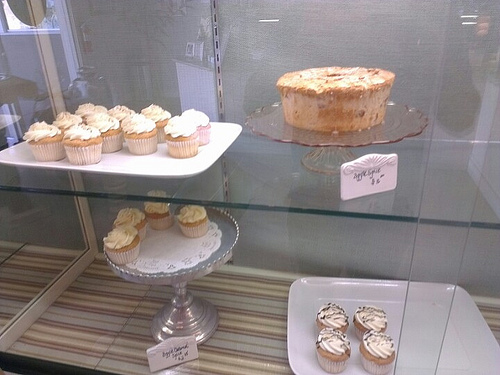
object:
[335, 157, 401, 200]
sign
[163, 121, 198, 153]
cupcake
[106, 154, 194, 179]
plate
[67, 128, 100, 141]
frosting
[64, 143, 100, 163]
cupcake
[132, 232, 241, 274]
platter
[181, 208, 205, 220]
frosting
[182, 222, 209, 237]
cupcake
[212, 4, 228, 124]
beam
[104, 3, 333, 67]
wall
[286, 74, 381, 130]
cake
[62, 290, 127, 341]
wall paper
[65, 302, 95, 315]
stripe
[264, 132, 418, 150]
platter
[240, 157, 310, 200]
shelf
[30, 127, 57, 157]
cupcake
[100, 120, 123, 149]
cupcake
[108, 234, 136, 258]
cupcake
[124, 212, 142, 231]
cupcake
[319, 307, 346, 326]
cupcake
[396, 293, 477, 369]
tray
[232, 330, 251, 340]
stripe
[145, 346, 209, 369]
sign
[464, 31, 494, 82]
reflection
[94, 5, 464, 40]
glass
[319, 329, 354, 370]
cupcake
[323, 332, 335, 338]
frosting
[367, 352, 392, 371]
cupcake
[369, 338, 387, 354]
frosting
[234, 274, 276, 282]
stripe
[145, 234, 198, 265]
doliy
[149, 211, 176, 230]
cupcake